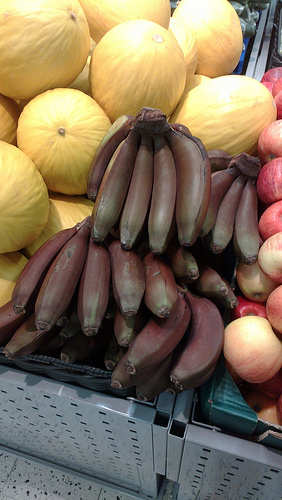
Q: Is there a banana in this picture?
A: Yes, there is a banana.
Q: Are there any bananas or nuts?
A: Yes, there is a banana.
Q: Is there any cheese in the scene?
A: No, there is no cheese.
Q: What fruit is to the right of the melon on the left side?
A: The fruit is a banana.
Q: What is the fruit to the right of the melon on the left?
A: The fruit is a banana.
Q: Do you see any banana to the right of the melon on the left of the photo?
A: Yes, there is a banana to the right of the melon.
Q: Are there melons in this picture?
A: Yes, there is a melon.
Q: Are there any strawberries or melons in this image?
A: Yes, there is a melon.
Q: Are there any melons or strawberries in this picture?
A: Yes, there is a melon.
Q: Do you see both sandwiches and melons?
A: No, there is a melon but no sandwiches.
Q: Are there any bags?
A: No, there are no bags.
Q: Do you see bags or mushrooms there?
A: No, there are no bags or mushrooms.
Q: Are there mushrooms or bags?
A: No, there are no bags or mushrooms.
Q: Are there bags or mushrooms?
A: No, there are no bags or mushrooms.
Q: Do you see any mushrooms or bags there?
A: No, there are no bags or mushrooms.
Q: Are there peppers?
A: No, there are no peppers.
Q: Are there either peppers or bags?
A: No, there are no peppers or bags.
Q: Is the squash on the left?
A: Yes, the squash is on the left of the image.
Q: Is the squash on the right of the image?
A: No, the squash is on the left of the image.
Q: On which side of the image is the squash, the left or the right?
A: The squash is on the left of the image.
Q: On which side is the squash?
A: The squash is on the left of the image.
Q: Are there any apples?
A: Yes, there is an apple.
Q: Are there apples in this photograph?
A: Yes, there is an apple.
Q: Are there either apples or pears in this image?
A: Yes, there is an apple.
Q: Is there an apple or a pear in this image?
A: Yes, there is an apple.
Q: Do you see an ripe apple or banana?
A: Yes, there is a ripe apple.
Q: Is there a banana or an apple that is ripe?
A: Yes, the apple is ripe.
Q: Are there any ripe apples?
A: Yes, there is a ripe apple.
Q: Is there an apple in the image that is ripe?
A: Yes, there is an apple that is ripe.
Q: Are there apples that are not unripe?
A: Yes, there is an ripe apple.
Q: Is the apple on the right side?
A: Yes, the apple is on the right of the image.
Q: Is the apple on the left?
A: No, the apple is on the right of the image.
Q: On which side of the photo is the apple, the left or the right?
A: The apple is on the right of the image.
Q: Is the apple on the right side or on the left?
A: The apple is on the right of the image.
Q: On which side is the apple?
A: The apple is on the right of the image.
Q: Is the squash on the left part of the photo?
A: Yes, the squash is on the left of the image.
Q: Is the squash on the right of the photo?
A: No, the squash is on the left of the image.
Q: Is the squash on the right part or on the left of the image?
A: The squash is on the left of the image.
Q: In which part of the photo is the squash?
A: The squash is on the left of the image.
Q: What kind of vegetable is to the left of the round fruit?
A: The vegetable is a squash.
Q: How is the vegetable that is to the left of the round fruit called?
A: The vegetable is a squash.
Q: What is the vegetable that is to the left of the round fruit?
A: The vegetable is a squash.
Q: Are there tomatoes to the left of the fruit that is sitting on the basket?
A: No, there is a squash to the left of the fruit.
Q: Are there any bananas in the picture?
A: Yes, there is a banana.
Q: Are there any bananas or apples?
A: Yes, there is a banana.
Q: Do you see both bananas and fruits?
A: Yes, there are both a banana and a fruit.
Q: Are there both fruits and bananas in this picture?
A: Yes, there are both a banana and a fruit.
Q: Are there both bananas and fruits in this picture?
A: Yes, there are both a banana and a fruit.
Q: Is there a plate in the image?
A: No, there are no plates.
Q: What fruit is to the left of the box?
A: The fruit is a banana.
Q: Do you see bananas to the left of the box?
A: Yes, there is a banana to the left of the box.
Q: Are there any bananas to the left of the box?
A: Yes, there is a banana to the left of the box.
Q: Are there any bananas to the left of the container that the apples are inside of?
A: Yes, there is a banana to the left of the box.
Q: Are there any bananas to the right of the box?
A: No, the banana is to the left of the box.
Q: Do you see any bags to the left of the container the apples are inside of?
A: No, there is a banana to the left of the box.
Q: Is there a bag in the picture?
A: No, there are no bags.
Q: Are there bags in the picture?
A: No, there are no bags.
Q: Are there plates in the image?
A: No, there are no plates.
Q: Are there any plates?
A: No, there are no plates.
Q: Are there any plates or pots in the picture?
A: No, there are no plates or pots.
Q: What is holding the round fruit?
A: The basket is holding the fruit.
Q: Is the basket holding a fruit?
A: Yes, the basket is holding a fruit.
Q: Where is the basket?
A: The basket is at the fruit stand.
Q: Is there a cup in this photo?
A: No, there are no cups.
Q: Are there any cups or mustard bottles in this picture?
A: No, there are no cups or mustard bottles.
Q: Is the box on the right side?
A: Yes, the box is on the right of the image.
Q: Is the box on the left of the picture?
A: No, the box is on the right of the image.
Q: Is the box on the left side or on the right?
A: The box is on the right of the image.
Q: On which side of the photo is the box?
A: The box is on the right of the image.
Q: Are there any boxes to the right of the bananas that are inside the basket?
A: Yes, there is a box to the right of the bananas.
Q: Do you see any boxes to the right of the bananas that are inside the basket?
A: Yes, there is a box to the right of the bananas.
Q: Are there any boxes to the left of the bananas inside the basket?
A: No, the box is to the right of the bananas.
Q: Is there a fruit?
A: Yes, there is a fruit.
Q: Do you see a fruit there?
A: Yes, there is a fruit.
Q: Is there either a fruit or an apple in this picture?
A: Yes, there is a fruit.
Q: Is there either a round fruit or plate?
A: Yes, there is a round fruit.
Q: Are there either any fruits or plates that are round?
A: Yes, the fruit is round.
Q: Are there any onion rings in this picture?
A: No, there are no onion rings.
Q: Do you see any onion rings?
A: No, there are no onion rings.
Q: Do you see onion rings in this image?
A: No, there are no onion rings.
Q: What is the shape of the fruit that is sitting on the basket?
A: The fruit is round.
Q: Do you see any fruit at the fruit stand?
A: Yes, there is a fruit at the fruit stand.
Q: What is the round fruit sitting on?
A: The fruit is sitting on the basket.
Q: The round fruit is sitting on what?
A: The fruit is sitting on the basket.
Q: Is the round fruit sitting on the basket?
A: Yes, the fruit is sitting on the basket.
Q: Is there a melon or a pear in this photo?
A: Yes, there are melons.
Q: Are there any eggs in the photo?
A: No, there are no eggs.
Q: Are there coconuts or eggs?
A: No, there are no eggs or coconuts.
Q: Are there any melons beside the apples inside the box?
A: Yes, there are melons beside the apples.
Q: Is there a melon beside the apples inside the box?
A: Yes, there are melons beside the apples.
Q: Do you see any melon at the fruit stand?
A: Yes, there are melons at the fruit stand.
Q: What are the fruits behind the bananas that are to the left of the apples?
A: The fruits are melons.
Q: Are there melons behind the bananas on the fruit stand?
A: Yes, there are melons behind the bananas.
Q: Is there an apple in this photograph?
A: Yes, there are apples.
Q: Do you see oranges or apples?
A: Yes, there are apples.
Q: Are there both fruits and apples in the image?
A: Yes, there are both apples and a fruit.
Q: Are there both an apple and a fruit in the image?
A: Yes, there are both an apple and a fruit.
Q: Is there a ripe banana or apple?
A: Yes, there are ripe apples.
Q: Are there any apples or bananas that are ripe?
A: Yes, the apples are ripe.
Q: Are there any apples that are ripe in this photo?
A: Yes, there are ripe apples.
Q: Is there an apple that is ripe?
A: Yes, there are apples that are ripe.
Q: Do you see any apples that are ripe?
A: Yes, there are apples that are ripe.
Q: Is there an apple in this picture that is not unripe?
A: Yes, there are ripe apples.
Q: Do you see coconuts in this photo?
A: No, there are no coconuts.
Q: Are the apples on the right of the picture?
A: Yes, the apples are on the right of the image.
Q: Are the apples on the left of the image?
A: No, the apples are on the right of the image.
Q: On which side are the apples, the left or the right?
A: The apples are on the right of the image.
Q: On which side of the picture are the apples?
A: The apples are on the right of the image.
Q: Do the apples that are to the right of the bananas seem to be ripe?
A: Yes, the apples are ripe.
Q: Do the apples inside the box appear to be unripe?
A: No, the apples are ripe.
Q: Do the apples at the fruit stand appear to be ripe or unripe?
A: The apples are ripe.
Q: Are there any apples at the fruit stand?
A: Yes, there are apples at the fruit stand.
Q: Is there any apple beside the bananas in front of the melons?
A: Yes, there are apples beside the bananas.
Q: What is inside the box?
A: The apples are inside the box.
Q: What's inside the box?
A: The apples are inside the box.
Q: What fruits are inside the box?
A: The fruits are apples.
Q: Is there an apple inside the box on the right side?
A: Yes, there are apples inside the box.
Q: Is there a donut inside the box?
A: No, there are apples inside the box.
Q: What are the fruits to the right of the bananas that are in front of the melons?
A: The fruits are apples.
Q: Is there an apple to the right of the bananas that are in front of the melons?
A: Yes, there are apples to the right of the bananas.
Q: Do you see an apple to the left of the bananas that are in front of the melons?
A: No, the apples are to the right of the bananas.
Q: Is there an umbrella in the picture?
A: No, there are no umbrellas.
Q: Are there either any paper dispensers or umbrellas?
A: No, there are no umbrellas or paper dispensers.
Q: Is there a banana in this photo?
A: Yes, there are bananas.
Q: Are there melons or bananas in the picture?
A: Yes, there are bananas.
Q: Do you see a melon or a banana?
A: Yes, there are bananas.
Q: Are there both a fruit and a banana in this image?
A: Yes, there are both a banana and a fruit.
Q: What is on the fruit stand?
A: The bananas are on the fruit stand.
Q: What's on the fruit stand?
A: The bananas are on the fruit stand.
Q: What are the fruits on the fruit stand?
A: The fruits are bananas.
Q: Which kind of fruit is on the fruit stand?
A: The fruits are bananas.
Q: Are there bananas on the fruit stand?
A: Yes, there are bananas on the fruit stand.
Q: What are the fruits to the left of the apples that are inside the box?
A: The fruits are bananas.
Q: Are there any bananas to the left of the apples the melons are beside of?
A: Yes, there are bananas to the left of the apples.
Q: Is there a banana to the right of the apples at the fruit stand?
A: No, the bananas are to the left of the apples.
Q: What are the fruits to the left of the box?
A: The fruits are bananas.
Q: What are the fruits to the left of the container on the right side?
A: The fruits are bananas.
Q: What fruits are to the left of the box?
A: The fruits are bananas.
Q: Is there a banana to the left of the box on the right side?
A: Yes, there are bananas to the left of the box.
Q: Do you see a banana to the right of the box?
A: No, the bananas are to the left of the box.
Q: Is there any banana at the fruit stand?
A: Yes, there are bananas at the fruit stand.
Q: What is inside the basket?
A: The bananas are inside the basket.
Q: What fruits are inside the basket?
A: The fruits are bananas.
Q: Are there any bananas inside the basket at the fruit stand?
A: Yes, there are bananas inside the basket.